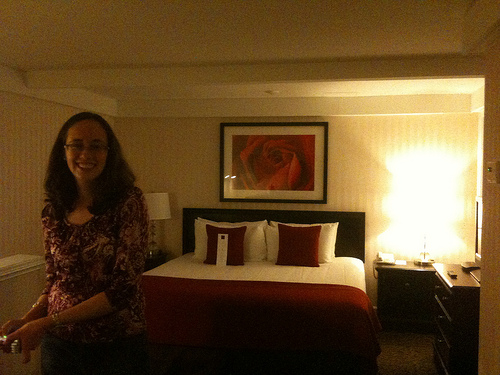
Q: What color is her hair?
A: Dark Brown.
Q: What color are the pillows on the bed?
A: Burgundy and white.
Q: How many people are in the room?
A: Two.